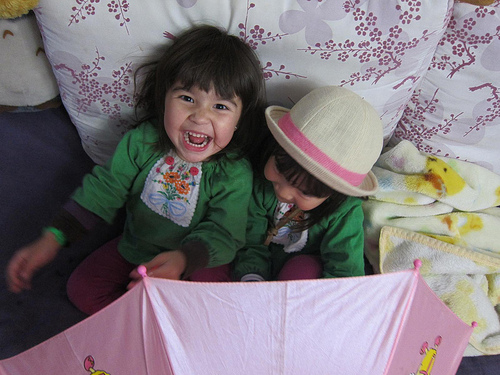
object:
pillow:
[386, 2, 500, 171]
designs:
[303, 0, 433, 85]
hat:
[261, 83, 387, 198]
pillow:
[25, 0, 455, 169]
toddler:
[37, 120, 254, 318]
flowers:
[147, 154, 198, 219]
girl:
[0, 27, 261, 316]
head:
[159, 32, 252, 166]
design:
[411, 333, 452, 374]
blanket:
[362, 139, 497, 360]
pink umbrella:
[0, 261, 477, 374]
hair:
[126, 23, 270, 163]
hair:
[266, 123, 350, 233]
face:
[265, 155, 330, 210]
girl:
[192, 85, 377, 293]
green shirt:
[234, 169, 368, 280]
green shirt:
[47, 120, 254, 280]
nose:
[189, 102, 212, 126]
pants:
[67, 236, 233, 315]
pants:
[184, 244, 325, 284]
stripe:
[275, 116, 367, 188]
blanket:
[33, 0, 457, 171]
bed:
[1, 0, 499, 373]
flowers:
[428, 6, 499, 79]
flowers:
[465, 79, 499, 135]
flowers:
[388, 86, 465, 157]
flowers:
[298, 1, 438, 89]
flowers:
[233, 2, 310, 82]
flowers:
[53, 46, 135, 116]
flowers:
[64, 0, 134, 38]